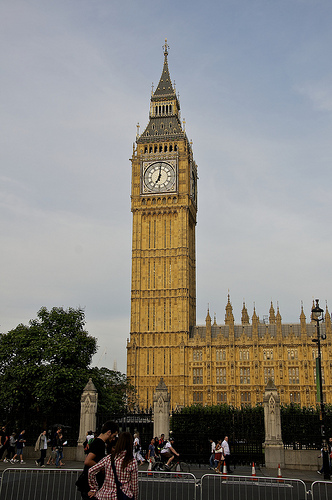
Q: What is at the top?
A: Steeple.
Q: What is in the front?
A: Fence.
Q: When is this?
A: Afternoon.